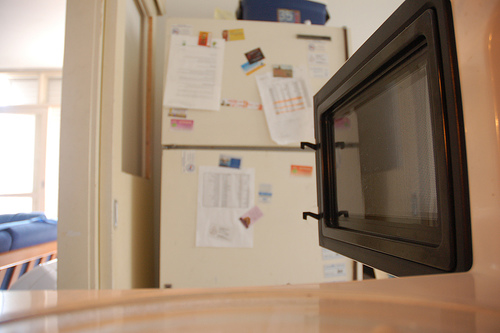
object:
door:
[295, 2, 476, 283]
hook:
[297, 137, 319, 156]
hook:
[300, 207, 325, 226]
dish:
[1, 283, 500, 332]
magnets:
[270, 60, 293, 81]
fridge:
[156, 13, 367, 291]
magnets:
[222, 26, 247, 45]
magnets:
[196, 28, 222, 51]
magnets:
[244, 44, 267, 67]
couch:
[1, 209, 61, 295]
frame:
[1, 238, 61, 293]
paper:
[162, 33, 230, 117]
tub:
[235, 1, 335, 30]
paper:
[254, 62, 324, 150]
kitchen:
[0, 1, 498, 332]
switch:
[112, 199, 122, 227]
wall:
[96, 1, 167, 292]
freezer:
[155, 13, 365, 155]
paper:
[193, 160, 259, 255]